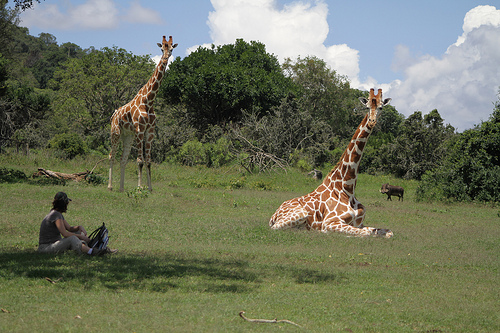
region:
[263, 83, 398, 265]
a giraffe is resting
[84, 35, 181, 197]
a giraffe is standing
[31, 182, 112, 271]
a man is sitting in the shade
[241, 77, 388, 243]
the giraffe has brown spots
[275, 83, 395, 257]
the giraffe has a long neck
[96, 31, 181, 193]
the giraffe has brown spots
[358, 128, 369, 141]
brown spot on giraffe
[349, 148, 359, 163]
brown spot on giraffe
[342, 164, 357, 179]
brown spot on giraffe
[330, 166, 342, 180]
brown spot on giraffe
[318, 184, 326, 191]
brown spot on giraffe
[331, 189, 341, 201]
brown spot on giraffe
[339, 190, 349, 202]
brown spot on giraffe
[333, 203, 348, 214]
brown spot on giraffe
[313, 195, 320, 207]
brown spot on giraffe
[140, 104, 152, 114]
brown spot on giraffe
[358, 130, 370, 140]
brown spot on giraffe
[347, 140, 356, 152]
brown spot on giraffe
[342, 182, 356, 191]
brown spot on giraffe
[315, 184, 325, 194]
brown spot on giraffe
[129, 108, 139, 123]
brown spot on giraffe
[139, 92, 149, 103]
brown spot on giraffe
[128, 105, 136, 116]
brown spot on giraffe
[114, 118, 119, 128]
brown spot on giraffe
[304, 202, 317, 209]
brown spot on giraffe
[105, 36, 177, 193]
giraffe is watching a man sit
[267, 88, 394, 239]
giraffe is watching a man sit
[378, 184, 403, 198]
boar is standing on a field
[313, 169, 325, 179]
boar is standing on a field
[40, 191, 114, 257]
man is sitting on the ground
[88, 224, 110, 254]
gray bookbag is sitting on the ground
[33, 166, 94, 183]
dead tree is lying on the ground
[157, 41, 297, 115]
tree is large and green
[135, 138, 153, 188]
giraffe has long spotted legs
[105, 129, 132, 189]
giraffe has long spotted legs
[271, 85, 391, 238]
a giraffe lying down in a field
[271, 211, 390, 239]
the legs of a giraffe lying down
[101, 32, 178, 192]
a giraffe standing in a field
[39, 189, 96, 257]
a man sitting in the grass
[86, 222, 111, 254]
a backpack on the ground in front of a man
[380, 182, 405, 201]
a wild hog standing in the distance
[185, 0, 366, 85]
an upward growing cloud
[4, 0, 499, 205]
trees and vegetation in a field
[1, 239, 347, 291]
the shadow of a tree on a ground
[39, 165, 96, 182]
a pile of wood on the ground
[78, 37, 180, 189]
tan and brown giraffe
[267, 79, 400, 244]
tan and brown spotted giraffe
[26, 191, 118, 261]
woman sitting in grass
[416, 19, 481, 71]
white clouds in blue sky